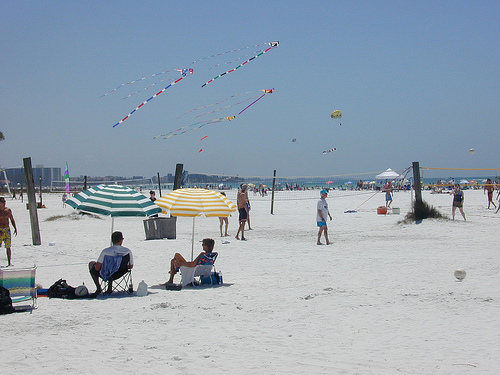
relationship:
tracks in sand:
[294, 285, 350, 308] [250, 269, 356, 341]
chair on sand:
[176, 236, 250, 292] [250, 269, 356, 341]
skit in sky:
[100, 31, 212, 136] [74, 5, 348, 167]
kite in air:
[155, 20, 301, 82] [74, 5, 348, 167]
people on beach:
[46, 178, 276, 317] [16, 72, 466, 368]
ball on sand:
[432, 235, 484, 286] [250, 269, 356, 341]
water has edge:
[316, 169, 329, 184] [298, 176, 334, 196]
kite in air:
[155, 20, 301, 82] [135, 20, 310, 144]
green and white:
[65, 178, 169, 255] [359, 166, 419, 195]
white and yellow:
[359, 166, 419, 195] [165, 183, 246, 226]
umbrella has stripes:
[145, 147, 250, 229] [168, 155, 238, 241]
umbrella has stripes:
[77, 165, 164, 223] [168, 155, 238, 241]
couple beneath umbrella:
[60, 222, 236, 313] [370, 149, 423, 184]